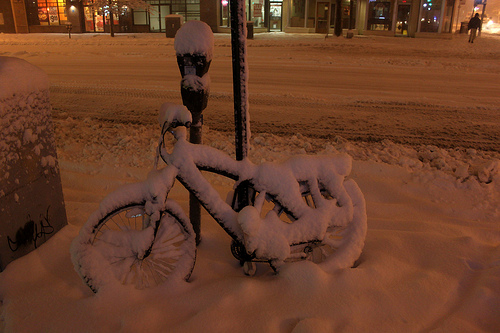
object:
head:
[474, 13, 479, 18]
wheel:
[72, 195, 198, 295]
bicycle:
[70, 103, 367, 299]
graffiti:
[2, 214, 73, 253]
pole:
[338, 15, 346, 32]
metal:
[226, 0, 249, 267]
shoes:
[468, 39, 474, 43]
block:
[0, 54, 70, 272]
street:
[0, 34, 499, 156]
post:
[226, 0, 248, 260]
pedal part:
[243, 259, 258, 276]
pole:
[187, 100, 207, 248]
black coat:
[468, 17, 481, 30]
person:
[468, 13, 484, 44]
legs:
[469, 27, 477, 40]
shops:
[0, 0, 500, 34]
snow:
[0, 30, 499, 332]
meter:
[168, 17, 216, 247]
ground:
[374, 97, 441, 137]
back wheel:
[236, 170, 369, 275]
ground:
[335, 274, 369, 316]